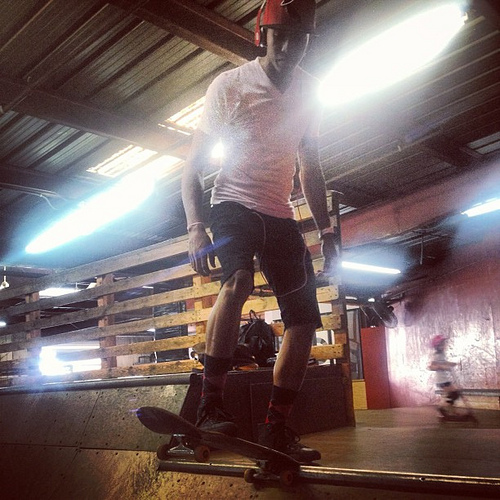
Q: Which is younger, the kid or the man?
A: The kid is younger than the man.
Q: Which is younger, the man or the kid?
A: The kid is younger than the man.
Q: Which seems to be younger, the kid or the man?
A: The kid is younger than the man.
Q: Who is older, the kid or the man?
A: The man is older than the kid.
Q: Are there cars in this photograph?
A: No, there are no cars.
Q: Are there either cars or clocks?
A: No, there are no cars or clocks.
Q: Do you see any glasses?
A: No, there are no glasses.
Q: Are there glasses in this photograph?
A: No, there are no glasses.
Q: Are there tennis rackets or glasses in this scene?
A: No, there are no glasses or tennis rackets.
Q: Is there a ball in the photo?
A: No, there are no balls.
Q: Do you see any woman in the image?
A: No, there are no women.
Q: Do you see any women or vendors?
A: No, there are no women or vendors.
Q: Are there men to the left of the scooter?
A: Yes, there is a man to the left of the scooter.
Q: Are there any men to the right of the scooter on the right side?
A: No, the man is to the left of the scooter.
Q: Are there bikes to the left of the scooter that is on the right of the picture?
A: No, there is a man to the left of the scooter.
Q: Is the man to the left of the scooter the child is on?
A: Yes, the man is to the left of the scooter.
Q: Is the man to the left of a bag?
A: No, the man is to the left of the scooter.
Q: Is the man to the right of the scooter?
A: No, the man is to the left of the scooter.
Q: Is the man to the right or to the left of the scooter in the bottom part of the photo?
A: The man is to the left of the scooter.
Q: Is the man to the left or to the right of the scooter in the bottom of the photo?
A: The man is to the left of the scooter.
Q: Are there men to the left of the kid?
A: Yes, there is a man to the left of the kid.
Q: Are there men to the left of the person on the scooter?
A: Yes, there is a man to the left of the kid.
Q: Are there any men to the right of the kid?
A: No, the man is to the left of the kid.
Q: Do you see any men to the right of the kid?
A: No, the man is to the left of the kid.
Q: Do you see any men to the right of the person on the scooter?
A: No, the man is to the left of the kid.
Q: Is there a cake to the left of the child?
A: No, there is a man to the left of the child.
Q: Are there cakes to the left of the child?
A: No, there is a man to the left of the child.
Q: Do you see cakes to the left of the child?
A: No, there is a man to the left of the child.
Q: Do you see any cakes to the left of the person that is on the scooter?
A: No, there is a man to the left of the child.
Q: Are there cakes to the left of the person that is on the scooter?
A: No, there is a man to the left of the child.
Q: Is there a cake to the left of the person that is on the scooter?
A: No, there is a man to the left of the child.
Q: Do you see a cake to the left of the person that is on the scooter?
A: No, there is a man to the left of the child.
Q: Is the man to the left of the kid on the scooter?
A: Yes, the man is to the left of the child.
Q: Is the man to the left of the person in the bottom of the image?
A: Yes, the man is to the left of the child.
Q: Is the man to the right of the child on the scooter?
A: No, the man is to the left of the child.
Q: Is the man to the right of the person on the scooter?
A: No, the man is to the left of the child.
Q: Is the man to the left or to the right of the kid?
A: The man is to the left of the kid.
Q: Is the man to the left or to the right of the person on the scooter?
A: The man is to the left of the kid.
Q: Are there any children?
A: Yes, there is a child.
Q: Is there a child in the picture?
A: Yes, there is a child.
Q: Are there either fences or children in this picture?
A: Yes, there is a child.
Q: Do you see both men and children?
A: Yes, there are both a child and a man.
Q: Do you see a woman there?
A: No, there are no women.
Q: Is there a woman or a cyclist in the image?
A: No, there are no women or cyclists.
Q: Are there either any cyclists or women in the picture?
A: No, there are no women or cyclists.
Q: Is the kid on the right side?
A: Yes, the kid is on the right of the image.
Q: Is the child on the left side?
A: No, the child is on the right of the image.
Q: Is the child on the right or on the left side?
A: The child is on the right of the image.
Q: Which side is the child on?
A: The child is on the right of the image.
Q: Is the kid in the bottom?
A: Yes, the kid is in the bottom of the image.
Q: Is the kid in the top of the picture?
A: No, the kid is in the bottom of the image.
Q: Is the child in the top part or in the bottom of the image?
A: The child is in the bottom of the image.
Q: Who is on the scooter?
A: The child is on the scooter.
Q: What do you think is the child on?
A: The child is on the scooter.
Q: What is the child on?
A: The child is on the scooter.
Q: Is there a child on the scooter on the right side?
A: Yes, there is a child on the scooter.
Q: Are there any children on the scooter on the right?
A: Yes, there is a child on the scooter.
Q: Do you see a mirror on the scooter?
A: No, there is a child on the scooter.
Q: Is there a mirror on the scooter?
A: No, there is a child on the scooter.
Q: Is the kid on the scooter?
A: Yes, the kid is on the scooter.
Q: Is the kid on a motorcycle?
A: No, the kid is on the scooter.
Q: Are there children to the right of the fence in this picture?
A: Yes, there is a child to the right of the fence.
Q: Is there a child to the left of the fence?
A: No, the child is to the right of the fence.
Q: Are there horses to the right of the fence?
A: No, there is a child to the right of the fence.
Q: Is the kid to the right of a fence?
A: Yes, the kid is to the right of a fence.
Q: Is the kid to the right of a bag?
A: No, the kid is to the right of a fence.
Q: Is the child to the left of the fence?
A: No, the child is to the right of the fence.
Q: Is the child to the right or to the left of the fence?
A: The child is to the right of the fence.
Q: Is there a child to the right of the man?
A: Yes, there is a child to the right of the man.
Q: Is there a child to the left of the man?
A: No, the child is to the right of the man.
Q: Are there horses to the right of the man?
A: No, there is a child to the right of the man.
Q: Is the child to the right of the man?
A: Yes, the child is to the right of the man.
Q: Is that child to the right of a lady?
A: No, the child is to the right of the man.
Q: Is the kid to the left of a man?
A: No, the kid is to the right of a man.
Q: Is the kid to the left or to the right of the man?
A: The kid is to the right of the man.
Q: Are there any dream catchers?
A: No, there are no dream catchers.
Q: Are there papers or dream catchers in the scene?
A: No, there are no dream catchers or papers.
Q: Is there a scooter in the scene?
A: Yes, there is a scooter.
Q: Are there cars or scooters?
A: Yes, there is a scooter.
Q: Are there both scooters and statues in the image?
A: No, there is a scooter but no statues.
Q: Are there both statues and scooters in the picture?
A: No, there is a scooter but no statues.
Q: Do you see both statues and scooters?
A: No, there is a scooter but no statues.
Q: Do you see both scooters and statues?
A: No, there is a scooter but no statues.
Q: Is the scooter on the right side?
A: Yes, the scooter is on the right of the image.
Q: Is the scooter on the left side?
A: No, the scooter is on the right of the image.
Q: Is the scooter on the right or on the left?
A: The scooter is on the right of the image.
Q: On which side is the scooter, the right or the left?
A: The scooter is on the right of the image.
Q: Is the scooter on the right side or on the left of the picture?
A: The scooter is on the right of the image.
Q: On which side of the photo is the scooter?
A: The scooter is on the right of the image.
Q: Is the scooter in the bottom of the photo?
A: Yes, the scooter is in the bottom of the image.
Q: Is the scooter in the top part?
A: No, the scooter is in the bottom of the image.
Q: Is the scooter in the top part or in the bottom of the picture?
A: The scooter is in the bottom of the image.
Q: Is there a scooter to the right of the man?
A: Yes, there is a scooter to the right of the man.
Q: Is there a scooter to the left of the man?
A: No, the scooter is to the right of the man.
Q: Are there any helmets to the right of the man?
A: No, there is a scooter to the right of the man.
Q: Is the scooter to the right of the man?
A: Yes, the scooter is to the right of the man.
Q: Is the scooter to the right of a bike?
A: No, the scooter is to the right of the man.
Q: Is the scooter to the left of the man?
A: No, the scooter is to the right of the man.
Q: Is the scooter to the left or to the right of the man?
A: The scooter is to the right of the man.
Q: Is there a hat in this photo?
A: Yes, there is a hat.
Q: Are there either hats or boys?
A: Yes, there is a hat.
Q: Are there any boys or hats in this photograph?
A: Yes, there is a hat.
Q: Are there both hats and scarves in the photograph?
A: No, there is a hat but no scarves.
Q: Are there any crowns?
A: No, there are no crowns.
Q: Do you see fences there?
A: Yes, there is a fence.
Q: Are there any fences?
A: Yes, there is a fence.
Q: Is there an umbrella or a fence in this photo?
A: Yes, there is a fence.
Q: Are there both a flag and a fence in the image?
A: No, there is a fence but no flags.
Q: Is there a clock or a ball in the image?
A: No, there are no balls or clocks.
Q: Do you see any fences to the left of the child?
A: Yes, there is a fence to the left of the child.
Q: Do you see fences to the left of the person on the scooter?
A: Yes, there is a fence to the left of the child.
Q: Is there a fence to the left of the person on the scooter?
A: Yes, there is a fence to the left of the child.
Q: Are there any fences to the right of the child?
A: No, the fence is to the left of the child.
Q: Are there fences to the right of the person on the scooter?
A: No, the fence is to the left of the child.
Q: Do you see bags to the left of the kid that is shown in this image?
A: No, there is a fence to the left of the kid.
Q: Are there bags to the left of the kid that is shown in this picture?
A: No, there is a fence to the left of the kid.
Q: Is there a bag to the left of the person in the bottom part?
A: No, there is a fence to the left of the kid.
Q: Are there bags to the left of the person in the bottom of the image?
A: No, there is a fence to the left of the kid.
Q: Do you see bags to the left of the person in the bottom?
A: No, there is a fence to the left of the kid.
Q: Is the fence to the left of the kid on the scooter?
A: Yes, the fence is to the left of the kid.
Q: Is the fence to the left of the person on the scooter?
A: Yes, the fence is to the left of the kid.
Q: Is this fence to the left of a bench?
A: No, the fence is to the left of the kid.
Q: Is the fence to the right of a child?
A: No, the fence is to the left of a child.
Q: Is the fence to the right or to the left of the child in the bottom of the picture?
A: The fence is to the left of the child.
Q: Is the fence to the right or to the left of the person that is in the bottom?
A: The fence is to the left of the child.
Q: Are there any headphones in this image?
A: Yes, there are headphones.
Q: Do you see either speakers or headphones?
A: Yes, there are headphones.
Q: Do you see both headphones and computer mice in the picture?
A: No, there are headphones but no computer mice.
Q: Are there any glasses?
A: No, there are no glasses.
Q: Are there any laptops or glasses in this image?
A: No, there are no glasses or laptops.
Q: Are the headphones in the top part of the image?
A: Yes, the headphones are in the top of the image.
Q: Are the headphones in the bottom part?
A: No, the headphones are in the top of the image.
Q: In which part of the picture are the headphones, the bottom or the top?
A: The headphones are in the top of the image.